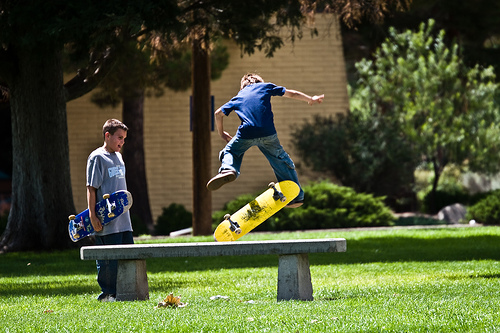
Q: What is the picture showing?
A: It is showing a park.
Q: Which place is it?
A: It is a park.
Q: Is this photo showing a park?
A: Yes, it is showing a park.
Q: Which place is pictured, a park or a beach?
A: It is a park.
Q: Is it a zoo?
A: No, it is a park.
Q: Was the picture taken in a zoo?
A: No, the picture was taken in a park.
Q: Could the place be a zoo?
A: No, it is a park.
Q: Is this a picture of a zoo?
A: No, the picture is showing a park.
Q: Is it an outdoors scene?
A: Yes, it is outdoors.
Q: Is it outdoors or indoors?
A: It is outdoors.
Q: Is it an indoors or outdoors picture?
A: It is outdoors.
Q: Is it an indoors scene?
A: No, it is outdoors.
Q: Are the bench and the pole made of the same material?
A: No, the bench is made of cement and the pole is made of wood.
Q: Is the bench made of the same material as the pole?
A: No, the bench is made of cement and the pole is made of wood.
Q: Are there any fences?
A: No, there are no fences.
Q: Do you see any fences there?
A: No, there are no fences.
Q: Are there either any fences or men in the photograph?
A: No, there are no fences or men.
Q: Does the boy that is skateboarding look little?
A: Yes, the boy is little.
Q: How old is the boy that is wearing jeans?
A: The boy is little.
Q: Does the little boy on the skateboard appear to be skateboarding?
A: Yes, the boy is skateboarding.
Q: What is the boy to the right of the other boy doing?
A: The boy is skateboarding.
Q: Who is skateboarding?
A: The boy is skateboarding.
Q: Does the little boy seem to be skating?
A: No, the boy is skateboarding.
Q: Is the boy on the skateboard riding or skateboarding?
A: The boy is skateboarding.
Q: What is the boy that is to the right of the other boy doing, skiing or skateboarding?
A: The boy is skateboarding.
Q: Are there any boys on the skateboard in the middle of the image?
A: Yes, there is a boy on the skateboard.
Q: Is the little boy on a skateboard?
A: Yes, the boy is on a skateboard.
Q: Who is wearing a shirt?
A: The boy is wearing a shirt.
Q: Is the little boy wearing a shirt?
A: Yes, the boy is wearing a shirt.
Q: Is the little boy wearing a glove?
A: No, the boy is wearing a shirt.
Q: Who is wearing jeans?
A: The boy is wearing jeans.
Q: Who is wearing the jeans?
A: The boy is wearing jeans.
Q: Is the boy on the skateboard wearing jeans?
A: Yes, the boy is wearing jeans.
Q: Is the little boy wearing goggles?
A: No, the boy is wearing jeans.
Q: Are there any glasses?
A: No, there are no glasses.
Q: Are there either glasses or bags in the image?
A: No, there are no glasses or bags.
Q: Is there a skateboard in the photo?
A: Yes, there is a skateboard.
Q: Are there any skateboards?
A: Yes, there is a skateboard.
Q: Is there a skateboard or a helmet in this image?
A: Yes, there is a skateboard.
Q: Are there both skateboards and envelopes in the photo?
A: No, there is a skateboard but no envelopes.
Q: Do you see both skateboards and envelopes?
A: No, there is a skateboard but no envelopes.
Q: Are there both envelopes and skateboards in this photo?
A: No, there is a skateboard but no envelopes.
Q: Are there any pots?
A: No, there are no pots.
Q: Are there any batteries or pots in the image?
A: No, there are no pots or batteries.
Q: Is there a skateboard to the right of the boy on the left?
A: Yes, there is a skateboard to the right of the boy.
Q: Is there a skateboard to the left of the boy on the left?
A: No, the skateboard is to the right of the boy.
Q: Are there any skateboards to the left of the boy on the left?
A: No, the skateboard is to the right of the boy.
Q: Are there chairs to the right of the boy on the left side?
A: No, there is a skateboard to the right of the boy.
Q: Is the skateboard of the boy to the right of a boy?
A: Yes, the skateboard is to the right of a boy.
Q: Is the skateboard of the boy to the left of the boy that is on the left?
A: No, the skateboard is to the right of the boy.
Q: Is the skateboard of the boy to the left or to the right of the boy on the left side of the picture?
A: The skateboard is to the right of the boy.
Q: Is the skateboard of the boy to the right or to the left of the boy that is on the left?
A: The skateboard is to the right of the boy.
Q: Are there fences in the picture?
A: No, there are no fences.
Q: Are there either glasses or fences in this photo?
A: No, there are no fences or glasses.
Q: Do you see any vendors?
A: No, there are no vendors.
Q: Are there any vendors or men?
A: No, there are no vendors or men.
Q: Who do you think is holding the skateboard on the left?
A: The boy is holding the skateboard.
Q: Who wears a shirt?
A: The boy wears a shirt.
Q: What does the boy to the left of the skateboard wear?
A: The boy wears a shirt.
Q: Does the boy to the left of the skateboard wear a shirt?
A: Yes, the boy wears a shirt.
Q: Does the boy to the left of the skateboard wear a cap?
A: No, the boy wears a shirt.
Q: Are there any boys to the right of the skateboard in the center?
A: No, the boy is to the left of the skateboard.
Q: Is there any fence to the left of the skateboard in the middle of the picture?
A: No, there is a boy to the left of the skateboard.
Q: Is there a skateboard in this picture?
A: Yes, there is a skateboard.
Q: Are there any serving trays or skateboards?
A: Yes, there is a skateboard.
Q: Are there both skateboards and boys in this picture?
A: Yes, there are both a skateboard and a boy.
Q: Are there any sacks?
A: No, there are no sacks.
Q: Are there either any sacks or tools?
A: No, there are no sacks or tools.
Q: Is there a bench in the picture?
A: Yes, there is a bench.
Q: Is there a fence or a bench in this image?
A: Yes, there is a bench.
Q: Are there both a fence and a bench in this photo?
A: No, there is a bench but no fences.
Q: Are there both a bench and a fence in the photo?
A: No, there is a bench but no fences.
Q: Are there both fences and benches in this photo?
A: No, there is a bench but no fences.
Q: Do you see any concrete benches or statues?
A: Yes, there is a concrete bench.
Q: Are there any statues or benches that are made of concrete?
A: Yes, the bench is made of concrete.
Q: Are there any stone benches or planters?
A: Yes, there is a stone bench.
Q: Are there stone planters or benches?
A: Yes, there is a stone bench.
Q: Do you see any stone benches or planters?
A: Yes, there is a stone bench.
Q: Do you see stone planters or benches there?
A: Yes, there is a stone bench.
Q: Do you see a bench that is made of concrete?
A: Yes, there is a bench that is made of concrete.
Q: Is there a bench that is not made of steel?
A: Yes, there is a bench that is made of cement.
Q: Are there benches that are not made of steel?
A: Yes, there is a bench that is made of cement.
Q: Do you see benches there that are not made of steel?
A: Yes, there is a bench that is made of cement.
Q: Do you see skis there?
A: No, there are no skis.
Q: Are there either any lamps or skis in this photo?
A: No, there are no skis or lamps.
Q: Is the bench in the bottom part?
A: Yes, the bench is in the bottom of the image.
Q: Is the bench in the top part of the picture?
A: No, the bench is in the bottom of the image.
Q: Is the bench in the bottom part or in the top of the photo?
A: The bench is in the bottom of the image.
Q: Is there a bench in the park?
A: Yes, there is a bench in the park.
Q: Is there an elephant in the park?
A: No, there is a bench in the park.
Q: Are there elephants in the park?
A: No, there is a bench in the park.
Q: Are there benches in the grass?
A: Yes, there is a bench in the grass.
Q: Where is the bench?
A: The bench is on the grass.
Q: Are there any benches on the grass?
A: Yes, there is a bench on the grass.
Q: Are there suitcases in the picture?
A: No, there are no suitcases.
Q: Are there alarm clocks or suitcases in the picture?
A: No, there are no suitcases or alarm clocks.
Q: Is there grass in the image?
A: Yes, there is grass.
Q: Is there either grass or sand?
A: Yes, there is grass.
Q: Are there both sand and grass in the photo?
A: No, there is grass but no sand.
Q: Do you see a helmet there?
A: No, there are no helmets.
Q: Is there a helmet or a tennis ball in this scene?
A: No, there are no helmets or tennis balls.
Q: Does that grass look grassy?
A: Yes, the grass is grassy.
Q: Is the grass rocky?
A: No, the grass is grassy.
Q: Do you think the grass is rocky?
A: No, the grass is grassy.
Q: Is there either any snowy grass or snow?
A: No, there is grass but it is grassy.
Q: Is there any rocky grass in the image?
A: No, there is grass but it is grassy.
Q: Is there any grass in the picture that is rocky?
A: No, there is grass but it is grassy.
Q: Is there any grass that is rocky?
A: No, there is grass but it is grassy.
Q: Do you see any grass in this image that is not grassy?
A: No, there is grass but it is grassy.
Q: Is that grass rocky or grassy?
A: The grass is grassy.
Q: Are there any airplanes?
A: No, there are no airplanes.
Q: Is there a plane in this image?
A: No, there are no airplanes.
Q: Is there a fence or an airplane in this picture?
A: No, there are no airplanes or fences.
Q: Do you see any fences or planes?
A: No, there are no planes or fences.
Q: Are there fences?
A: No, there are no fences.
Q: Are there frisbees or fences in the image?
A: No, there are no fences or frisbees.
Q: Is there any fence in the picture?
A: No, there are no fences.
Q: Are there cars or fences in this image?
A: No, there are no fences or cars.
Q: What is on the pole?
A: The sign is on the pole.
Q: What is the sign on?
A: The sign is on the pole.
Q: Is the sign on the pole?
A: Yes, the sign is on the pole.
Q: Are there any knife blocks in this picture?
A: No, there are no knife blocks.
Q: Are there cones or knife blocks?
A: No, there are no knife blocks or cones.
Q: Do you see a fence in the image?
A: No, there are no fences.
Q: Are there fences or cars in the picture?
A: No, there are no fences or cars.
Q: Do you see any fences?
A: No, there are no fences.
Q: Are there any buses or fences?
A: No, there are no fences or buses.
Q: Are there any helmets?
A: No, there are no helmets.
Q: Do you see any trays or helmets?
A: No, there are no helmets or trays.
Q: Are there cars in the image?
A: No, there are no cars.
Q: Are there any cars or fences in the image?
A: No, there are no cars or fences.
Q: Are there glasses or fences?
A: No, there are no fences or glasses.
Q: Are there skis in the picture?
A: No, there are no skis.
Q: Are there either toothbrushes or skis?
A: No, there are no skis or toothbrushes.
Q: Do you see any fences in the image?
A: No, there are no fences.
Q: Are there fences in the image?
A: No, there are no fences.